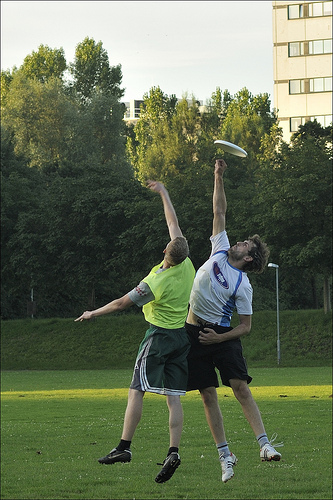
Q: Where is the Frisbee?
A: In the air.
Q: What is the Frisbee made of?
A: Plastic.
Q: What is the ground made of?
A: Grass.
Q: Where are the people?
A: Above the grass.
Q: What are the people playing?
A: Frisbee.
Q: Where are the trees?
A: Behind the field.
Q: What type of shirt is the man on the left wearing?
A: A green short sleeved shirt.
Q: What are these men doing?
A: Playing frisbee.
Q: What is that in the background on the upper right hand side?
A: A building.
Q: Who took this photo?
A: Another frisbee player.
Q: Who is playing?
A: Two men.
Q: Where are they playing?
A: In a park.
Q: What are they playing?
A: Frisbee.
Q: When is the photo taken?
A: During the day.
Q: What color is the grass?
A: Green.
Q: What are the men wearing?
A: T-shirts and shorts.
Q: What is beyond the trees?
A: A tall building.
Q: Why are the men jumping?
A: To grab the Frisbee.